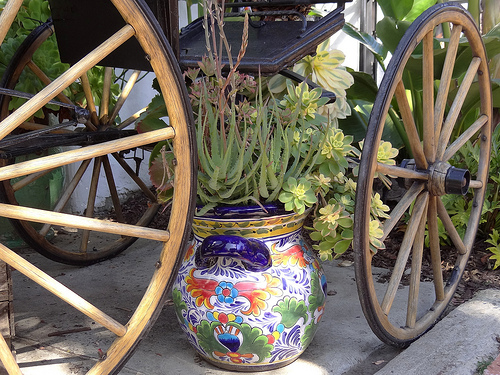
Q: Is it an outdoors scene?
A: Yes, it is outdoors.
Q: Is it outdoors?
A: Yes, it is outdoors.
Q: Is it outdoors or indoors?
A: It is outdoors.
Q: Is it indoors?
A: No, it is outdoors.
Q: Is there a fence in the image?
A: No, there are no fences.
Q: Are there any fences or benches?
A: No, there are no fences or benches.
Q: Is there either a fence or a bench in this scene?
A: No, there are no fences or benches.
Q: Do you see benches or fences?
A: No, there are no fences or benches.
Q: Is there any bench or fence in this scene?
A: No, there are no fences or benches.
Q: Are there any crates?
A: No, there are no crates.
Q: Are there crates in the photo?
A: No, there are no crates.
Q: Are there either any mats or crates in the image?
A: No, there are no crates or mats.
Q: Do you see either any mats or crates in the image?
A: No, there are no crates or mats.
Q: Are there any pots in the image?
A: Yes, there is a pot.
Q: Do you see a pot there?
A: Yes, there is a pot.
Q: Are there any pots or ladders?
A: Yes, there is a pot.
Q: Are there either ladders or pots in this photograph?
A: Yes, there is a pot.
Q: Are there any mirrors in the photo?
A: No, there are no mirrors.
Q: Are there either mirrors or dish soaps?
A: No, there are no mirrors or dish soaps.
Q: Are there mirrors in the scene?
A: No, there are no mirrors.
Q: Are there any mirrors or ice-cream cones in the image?
A: No, there are no mirrors or ice-cream cones.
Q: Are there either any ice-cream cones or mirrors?
A: No, there are no mirrors or ice-cream cones.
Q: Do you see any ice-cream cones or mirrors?
A: No, there are no mirrors or ice-cream cones.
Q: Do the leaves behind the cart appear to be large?
A: Yes, the leaves are large.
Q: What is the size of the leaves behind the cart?
A: The leaves are large.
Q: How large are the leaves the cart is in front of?
A: The leaves are large.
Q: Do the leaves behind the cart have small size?
A: No, the leaves are large.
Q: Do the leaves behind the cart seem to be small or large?
A: The leaves are large.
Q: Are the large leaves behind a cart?
A: Yes, the leaves are behind a cart.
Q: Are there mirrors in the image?
A: No, there are no mirrors.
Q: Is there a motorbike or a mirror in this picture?
A: No, there are no mirrors or motorcycles.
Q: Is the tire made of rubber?
A: Yes, the tire is made of rubber.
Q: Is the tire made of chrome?
A: No, the tire is made of rubber.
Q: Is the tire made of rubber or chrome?
A: The tire is made of rubber.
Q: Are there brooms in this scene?
A: No, there are no brooms.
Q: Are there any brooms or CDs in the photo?
A: No, there are no brooms or cds.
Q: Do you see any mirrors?
A: No, there are no mirrors.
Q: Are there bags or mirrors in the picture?
A: No, there are no mirrors or bags.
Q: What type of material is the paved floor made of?
A: The floor is made of concrete.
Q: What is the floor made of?
A: The floor is made of concrete.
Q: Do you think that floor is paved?
A: Yes, the floor is paved.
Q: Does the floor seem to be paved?
A: Yes, the floor is paved.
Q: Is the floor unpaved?
A: No, the floor is paved.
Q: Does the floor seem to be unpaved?
A: No, the floor is paved.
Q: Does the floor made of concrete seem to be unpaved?
A: No, the floor is paved.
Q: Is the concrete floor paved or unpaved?
A: The floor is paved.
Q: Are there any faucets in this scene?
A: No, there are no faucets.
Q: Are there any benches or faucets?
A: No, there are no faucets or benches.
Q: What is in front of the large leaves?
A: The cart is in front of the leaves.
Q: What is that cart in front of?
A: The cart is in front of the leaves.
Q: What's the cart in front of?
A: The cart is in front of the leaves.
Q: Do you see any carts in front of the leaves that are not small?
A: Yes, there is a cart in front of the leaves.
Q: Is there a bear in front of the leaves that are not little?
A: No, there is a cart in front of the leaves.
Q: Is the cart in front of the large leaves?
A: Yes, the cart is in front of the leaves.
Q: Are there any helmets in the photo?
A: No, there are no helmets.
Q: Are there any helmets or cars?
A: No, there are no helmets or cars.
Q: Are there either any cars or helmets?
A: No, there are no helmets or cars.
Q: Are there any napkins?
A: No, there are no napkins.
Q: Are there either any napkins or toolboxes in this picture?
A: No, there are no napkins or toolboxes.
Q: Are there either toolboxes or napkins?
A: No, there are no napkins or toolboxes.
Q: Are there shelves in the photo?
A: No, there are no shelves.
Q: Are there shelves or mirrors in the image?
A: No, there are no shelves or mirrors.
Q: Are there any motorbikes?
A: No, there are no motorbikes.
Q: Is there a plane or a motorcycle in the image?
A: No, there are no motorcycles or airplanes.